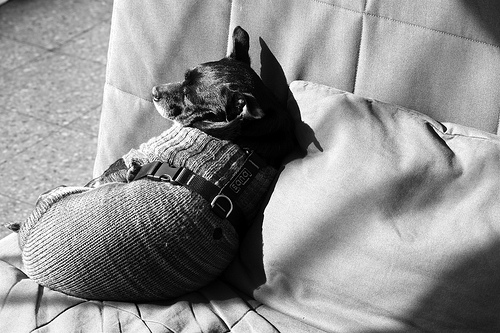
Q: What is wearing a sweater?
A: Dog.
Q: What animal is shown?
A: Dog.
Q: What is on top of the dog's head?
A: Ears.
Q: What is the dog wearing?
A: Sweater.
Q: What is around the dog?
A: Harness.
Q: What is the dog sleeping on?
A: Pillow.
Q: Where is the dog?
A: Couch.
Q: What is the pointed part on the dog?
A: Nose.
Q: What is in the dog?
A: A harness.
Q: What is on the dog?
A: A sweater.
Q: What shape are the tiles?
A: Square.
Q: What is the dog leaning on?
A: Pillow.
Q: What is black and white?
A: The entire photo.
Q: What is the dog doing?
A: Laying.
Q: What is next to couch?
A: Tile.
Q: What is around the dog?
A: A buckle.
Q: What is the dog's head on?
A: A pillow.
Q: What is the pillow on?
A: A bed.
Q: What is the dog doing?
A: Resting.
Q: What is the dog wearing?
A: A sweater.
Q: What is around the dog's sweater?
A: A strap.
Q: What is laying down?
A: A dog.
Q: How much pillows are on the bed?
A: One.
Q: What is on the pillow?
A: A dog.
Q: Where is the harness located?
A: Around the dog.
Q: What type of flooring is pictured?
A: Tile.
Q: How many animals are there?
A: 1.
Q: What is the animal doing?
A: Laying down.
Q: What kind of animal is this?
A: Dog.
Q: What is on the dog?
A: Sweater.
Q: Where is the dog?
A: On the couch.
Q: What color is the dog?
A: Black.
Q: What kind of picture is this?
A: Black and white.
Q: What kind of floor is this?
A: Tile.